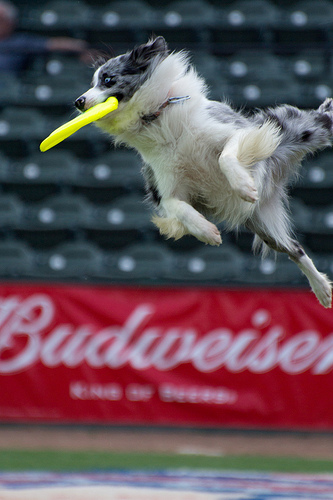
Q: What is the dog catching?
A: A frisbee.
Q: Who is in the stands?
A: A solitary person watching the exhibition.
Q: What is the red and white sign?
A: A budweiser advertisement banner.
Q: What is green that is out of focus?
A: A patch of grass.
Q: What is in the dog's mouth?
A: A yellow frisbee.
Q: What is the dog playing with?
A: A frisbee.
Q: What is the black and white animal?
A: A dog.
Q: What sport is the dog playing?
A: Frisbee.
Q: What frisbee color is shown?
A: Yellow.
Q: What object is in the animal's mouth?
A: Frisbee.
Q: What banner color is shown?
A: Red and white.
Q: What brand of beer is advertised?
A: Budweiser.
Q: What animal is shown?
A: A dog.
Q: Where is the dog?
A: In the air.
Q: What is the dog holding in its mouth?
A: Frisbee.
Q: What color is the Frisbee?
A: Yellow.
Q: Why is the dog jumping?
A: To catch the Frisbee.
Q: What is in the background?
A: Arena Seats.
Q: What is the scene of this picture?
A: In an arena.